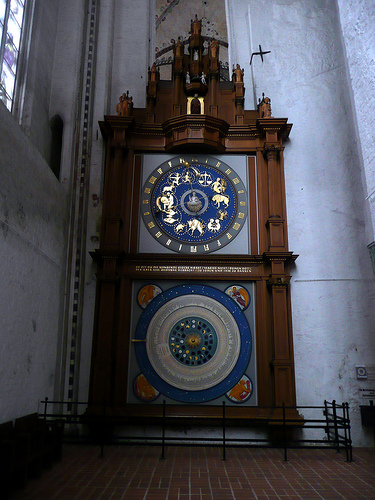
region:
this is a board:
[96, 47, 286, 402]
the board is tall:
[108, 124, 276, 414]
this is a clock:
[138, 161, 251, 248]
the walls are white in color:
[302, 1, 371, 237]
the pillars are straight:
[268, 249, 289, 404]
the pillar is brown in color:
[269, 257, 289, 400]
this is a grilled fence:
[321, 404, 346, 451]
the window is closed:
[0, 2, 30, 101]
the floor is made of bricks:
[199, 468, 278, 498]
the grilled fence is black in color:
[325, 406, 345, 447]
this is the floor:
[159, 470, 249, 494]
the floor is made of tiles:
[138, 465, 220, 498]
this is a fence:
[209, 395, 335, 463]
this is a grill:
[221, 405, 226, 458]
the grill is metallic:
[220, 408, 226, 451]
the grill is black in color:
[222, 400, 227, 458]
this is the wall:
[308, 349, 332, 381]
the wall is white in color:
[307, 357, 331, 390]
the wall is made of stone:
[302, 353, 333, 388]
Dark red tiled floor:
[65, 458, 308, 499]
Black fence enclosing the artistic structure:
[39, 398, 351, 459]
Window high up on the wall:
[0, 0, 40, 110]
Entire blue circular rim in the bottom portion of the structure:
[131, 280, 242, 395]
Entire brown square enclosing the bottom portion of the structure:
[86, 251, 296, 420]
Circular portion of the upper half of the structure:
[142, 153, 250, 251]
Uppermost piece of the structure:
[186, 13, 202, 46]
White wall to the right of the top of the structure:
[276, 8, 337, 113]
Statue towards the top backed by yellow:
[185, 91, 203, 111]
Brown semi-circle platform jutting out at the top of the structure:
[159, 114, 230, 149]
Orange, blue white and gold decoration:
[137, 279, 252, 401]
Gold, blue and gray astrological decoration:
[143, 157, 251, 253]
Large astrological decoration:
[148, 153, 245, 248]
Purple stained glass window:
[5, 2, 40, 136]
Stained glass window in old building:
[5, 1, 36, 137]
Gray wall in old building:
[286, 7, 356, 111]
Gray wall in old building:
[307, 129, 358, 345]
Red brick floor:
[102, 455, 240, 495]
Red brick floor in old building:
[214, 463, 360, 496]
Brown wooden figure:
[105, 77, 131, 117]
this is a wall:
[301, 153, 345, 313]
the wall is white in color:
[306, 355, 317, 383]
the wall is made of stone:
[306, 347, 323, 378]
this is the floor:
[116, 472, 193, 498]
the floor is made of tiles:
[112, 460, 191, 488]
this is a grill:
[222, 402, 346, 450]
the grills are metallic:
[222, 400, 226, 450]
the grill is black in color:
[219, 402, 229, 453]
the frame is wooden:
[266, 353, 283, 388]